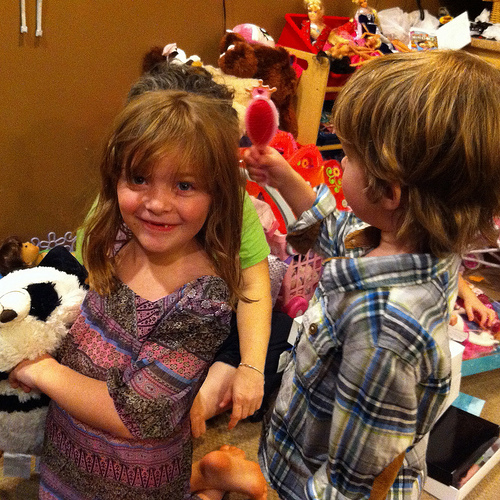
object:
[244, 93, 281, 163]
brush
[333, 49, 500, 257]
hair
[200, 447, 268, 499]
feet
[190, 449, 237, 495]
ankles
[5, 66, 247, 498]
girl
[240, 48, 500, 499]
boy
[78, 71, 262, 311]
hair